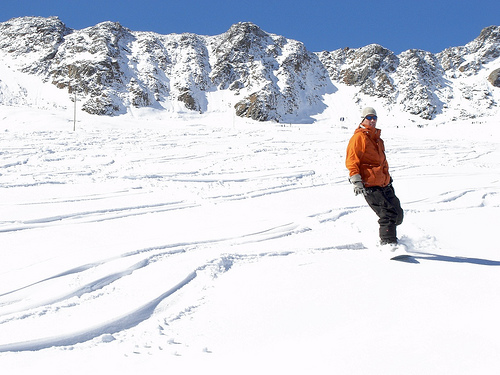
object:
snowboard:
[383, 243, 415, 260]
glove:
[346, 174, 364, 196]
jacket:
[344, 124, 390, 190]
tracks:
[0, 178, 499, 354]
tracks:
[0, 149, 495, 234]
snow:
[0, 52, 498, 374]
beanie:
[359, 107, 377, 121]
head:
[356, 106, 378, 129]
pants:
[362, 184, 404, 245]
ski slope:
[0, 102, 499, 374]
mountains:
[0, 16, 499, 123]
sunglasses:
[364, 116, 378, 122]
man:
[343, 105, 405, 251]